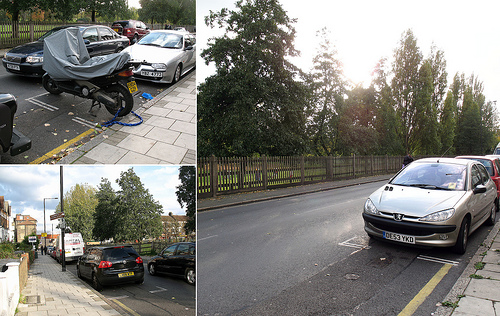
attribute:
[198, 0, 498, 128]
sky — grey 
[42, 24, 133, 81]
cover —  grey  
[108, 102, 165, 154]
cord — blue 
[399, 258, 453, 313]
line — yellow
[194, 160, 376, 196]
grass — green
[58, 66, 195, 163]
sidewalk — concrete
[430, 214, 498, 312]
sidewalk — concrete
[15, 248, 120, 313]
sidewalk — concrete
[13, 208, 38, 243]
building — in area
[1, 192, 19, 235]
building — in area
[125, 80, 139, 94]
plate — yelow license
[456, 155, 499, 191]
car — red,  silver 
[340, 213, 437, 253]
plate — yellow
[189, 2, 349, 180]
tree — green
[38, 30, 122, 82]
cover — gray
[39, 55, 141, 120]
motorcycle — black, grey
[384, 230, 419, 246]
plate — License 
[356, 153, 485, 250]
car — gray